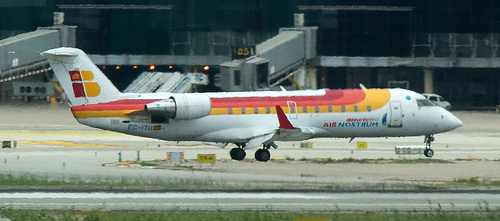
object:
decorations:
[67, 68, 391, 119]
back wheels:
[230, 142, 279, 162]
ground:
[0, 166, 500, 219]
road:
[0, 188, 500, 213]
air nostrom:
[322, 118, 380, 128]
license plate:
[128, 124, 153, 131]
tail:
[39, 46, 121, 105]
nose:
[415, 108, 464, 136]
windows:
[416, 99, 434, 106]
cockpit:
[399, 89, 449, 120]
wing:
[242, 129, 280, 150]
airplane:
[39, 47, 463, 162]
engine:
[144, 94, 212, 120]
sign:
[196, 154, 215, 162]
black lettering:
[199, 156, 213, 161]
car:
[420, 93, 452, 111]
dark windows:
[430, 96, 437, 101]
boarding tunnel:
[215, 12, 319, 93]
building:
[1, 1, 498, 106]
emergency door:
[287, 101, 297, 120]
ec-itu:
[127, 124, 152, 130]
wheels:
[229, 147, 246, 160]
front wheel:
[424, 149, 435, 157]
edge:
[0, 184, 500, 191]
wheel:
[254, 149, 270, 162]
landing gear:
[262, 142, 278, 149]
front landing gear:
[424, 134, 435, 157]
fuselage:
[69, 87, 463, 140]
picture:
[1, 0, 499, 220]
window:
[367, 105, 372, 112]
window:
[341, 106, 346, 112]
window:
[328, 106, 333, 113]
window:
[315, 107, 320, 114]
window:
[302, 107, 307, 113]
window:
[266, 107, 271, 114]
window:
[254, 107, 260, 114]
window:
[241, 108, 246, 115]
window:
[228, 108, 234, 115]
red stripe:
[101, 84, 344, 104]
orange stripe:
[71, 88, 366, 111]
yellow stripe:
[72, 87, 390, 118]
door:
[388, 101, 405, 128]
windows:
[353, 105, 358, 112]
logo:
[68, 70, 101, 98]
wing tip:
[274, 104, 296, 129]